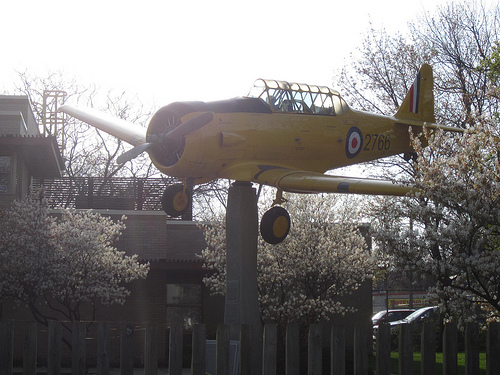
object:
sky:
[11, 0, 497, 215]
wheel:
[162, 183, 191, 217]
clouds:
[5, 0, 428, 86]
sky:
[8, 0, 499, 88]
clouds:
[12, 0, 472, 90]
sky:
[8, 0, 488, 128]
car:
[371, 306, 500, 349]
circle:
[345, 126, 364, 159]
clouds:
[54, 16, 151, 53]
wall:
[125, 215, 165, 265]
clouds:
[12, 15, 135, 73]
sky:
[4, 0, 330, 55]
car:
[371, 308, 418, 332]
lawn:
[377, 350, 490, 370]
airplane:
[54, 63, 476, 245]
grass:
[399, 351, 498, 370]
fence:
[2, 315, 500, 375]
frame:
[243, 75, 351, 117]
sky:
[0, 21, 496, 243]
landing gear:
[259, 205, 291, 245]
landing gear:
[161, 182, 193, 219]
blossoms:
[365, 119, 498, 317]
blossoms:
[194, 184, 377, 320]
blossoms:
[3, 190, 150, 305]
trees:
[406, 120, 500, 337]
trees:
[0, 192, 153, 352]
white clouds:
[330, 2, 358, 29]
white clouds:
[260, 38, 289, 62]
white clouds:
[155, 35, 180, 56]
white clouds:
[110, 8, 142, 48]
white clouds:
[30, 20, 64, 47]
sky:
[0, 0, 396, 110]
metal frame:
[42, 89, 64, 156]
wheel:
[260, 206, 291, 245]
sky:
[3, 17, 498, 224]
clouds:
[37, 46, 276, 80]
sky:
[29, 7, 444, 108]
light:
[41, 0, 287, 79]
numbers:
[363, 133, 391, 150]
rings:
[347, 131, 361, 154]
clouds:
[57, 33, 331, 75]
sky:
[30, 53, 356, 91]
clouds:
[87, 0, 364, 87]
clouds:
[33, 24, 371, 89]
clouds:
[24, 10, 362, 79]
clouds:
[37, 4, 349, 76]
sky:
[11, 7, 483, 80]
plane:
[57, 62, 481, 246]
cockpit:
[247, 77, 349, 116]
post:
[223, 181, 260, 375]